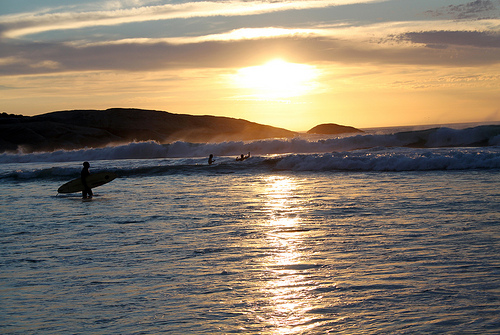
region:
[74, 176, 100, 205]
the leg of a man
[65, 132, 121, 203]
the body of a man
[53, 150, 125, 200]
a man holding a surfboard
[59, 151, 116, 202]
a man in the water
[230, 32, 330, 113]
the sun in the sky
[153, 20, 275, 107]
clouds in the sky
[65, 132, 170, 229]
a man in the ocean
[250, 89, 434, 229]
a wave in the ocean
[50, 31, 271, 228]
a mountain in the background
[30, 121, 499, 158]
a large wave in approaching the shore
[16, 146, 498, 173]
a smaller wave is nearer the shore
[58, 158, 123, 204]
person with a surfboard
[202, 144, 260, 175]
people in the closer wave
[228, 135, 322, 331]
sun shines on the water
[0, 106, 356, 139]
the hill on the far shore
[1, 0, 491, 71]
strips of clouds in the sky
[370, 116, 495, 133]
the water line on the horizon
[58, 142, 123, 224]
surfer carries board through shallow water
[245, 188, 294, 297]
sun on the water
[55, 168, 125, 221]
surfer standing in the ocean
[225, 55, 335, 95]
sun in the sky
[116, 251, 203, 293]
the water is calm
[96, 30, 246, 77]
clouds in the sky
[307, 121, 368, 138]
mountain in the distance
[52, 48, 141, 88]
the clouds are grey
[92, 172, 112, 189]
this is a surfboard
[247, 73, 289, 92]
the sun is yellow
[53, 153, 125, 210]
A man with a surfboard.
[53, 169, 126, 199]
A large surfboard in the man's arms.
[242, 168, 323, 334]
Light reflects off of the water.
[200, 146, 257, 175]
Two people swim in ocean.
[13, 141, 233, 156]
A small wave forms on the water.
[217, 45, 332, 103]
The sun shines through dark clouds.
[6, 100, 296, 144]
A large hill on the shore.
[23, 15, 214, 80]
Dark clouds in the sky.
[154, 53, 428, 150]
the sun is setting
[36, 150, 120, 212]
a person in the water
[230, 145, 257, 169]
the person is falling